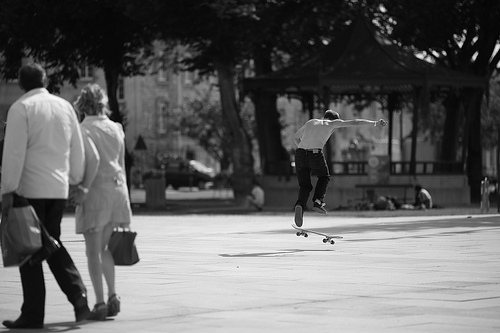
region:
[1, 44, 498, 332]
The photograph is in black and white.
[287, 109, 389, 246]
The man is jumping off his skateboard.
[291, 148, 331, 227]
The man has on black jeans.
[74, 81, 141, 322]
The woman is carrying a purse.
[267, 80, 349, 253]
the man is skateboarding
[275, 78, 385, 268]
the man is skateboarding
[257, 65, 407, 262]
the man is skateboarding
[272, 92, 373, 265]
the man is skateboarding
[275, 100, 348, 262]
the man is skateboarding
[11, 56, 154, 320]
a couple is watching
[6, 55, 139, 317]
a couple is watching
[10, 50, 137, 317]
a couple is watching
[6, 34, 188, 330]
a couple is watching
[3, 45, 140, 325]
a couple is watching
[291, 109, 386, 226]
a shirtless skateboarder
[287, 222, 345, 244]
a skateboard in mid air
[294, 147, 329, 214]
a pair of black jeans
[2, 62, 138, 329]
a couple walking holding hands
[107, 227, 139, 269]
a large women's purse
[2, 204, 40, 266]
a large shopping bag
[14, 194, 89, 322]
a pair of black pants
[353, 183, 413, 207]
a picnic table in distance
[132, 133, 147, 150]
a traffic yield sign in distance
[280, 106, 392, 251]
man jumping in the air over skateboard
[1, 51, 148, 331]
two people walking across skatepark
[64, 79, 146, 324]
woman holding handbag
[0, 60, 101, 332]
man holding bags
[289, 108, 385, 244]
a guy is skate boarding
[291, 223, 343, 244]
the skateboard is mid air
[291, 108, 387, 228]
the man is mid air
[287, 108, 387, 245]
the man is above the skateboard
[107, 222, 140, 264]
the handbag is dark colored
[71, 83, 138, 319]
the woman is carrying the bag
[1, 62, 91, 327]
the man is carrying a bag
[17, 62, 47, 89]
the hair is dark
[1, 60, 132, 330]
the man and woman are holding hands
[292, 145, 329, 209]
the pants are dark